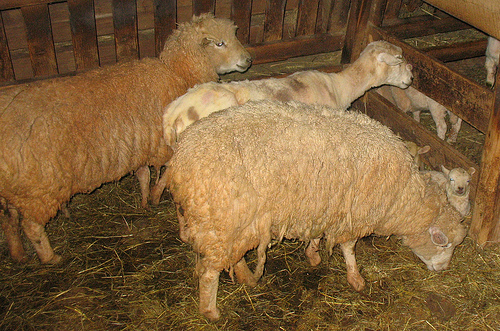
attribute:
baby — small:
[426, 156, 480, 225]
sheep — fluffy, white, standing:
[146, 91, 473, 327]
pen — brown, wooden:
[66, 4, 106, 74]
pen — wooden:
[106, 0, 146, 58]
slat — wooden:
[257, 0, 289, 49]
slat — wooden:
[273, 2, 302, 43]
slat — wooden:
[188, 4, 220, 16]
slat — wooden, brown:
[230, 2, 255, 49]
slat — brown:
[15, 2, 58, 80]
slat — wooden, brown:
[321, 2, 346, 32]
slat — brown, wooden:
[2, 5, 38, 86]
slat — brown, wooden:
[364, 14, 498, 128]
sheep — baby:
[426, 154, 478, 224]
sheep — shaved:
[152, 34, 419, 117]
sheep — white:
[162, 95, 472, 317]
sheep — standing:
[159, 29, 436, 187]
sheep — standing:
[1, 5, 265, 268]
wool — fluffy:
[158, 96, 471, 319]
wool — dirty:
[0, 7, 269, 272]